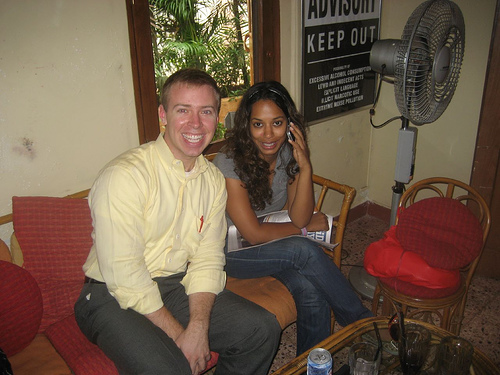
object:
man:
[73, 68, 283, 375]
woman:
[211, 80, 379, 358]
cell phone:
[286, 122, 295, 142]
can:
[306, 347, 332, 375]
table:
[267, 315, 500, 375]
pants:
[224, 236, 376, 355]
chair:
[371, 177, 491, 335]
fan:
[369, 0, 465, 226]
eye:
[177, 108, 189, 113]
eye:
[201, 110, 212, 115]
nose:
[188, 113, 202, 129]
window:
[148, 0, 257, 144]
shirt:
[81, 131, 228, 315]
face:
[168, 88, 218, 155]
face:
[250, 102, 288, 154]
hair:
[225, 80, 304, 211]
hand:
[175, 333, 211, 374]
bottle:
[438, 336, 474, 375]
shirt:
[211, 143, 298, 253]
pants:
[74, 274, 284, 375]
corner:
[356, 154, 387, 217]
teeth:
[183, 133, 205, 142]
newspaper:
[228, 209, 340, 252]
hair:
[160, 68, 221, 112]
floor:
[268, 214, 500, 375]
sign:
[298, 0, 380, 129]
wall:
[280, 0, 481, 227]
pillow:
[396, 196, 483, 271]